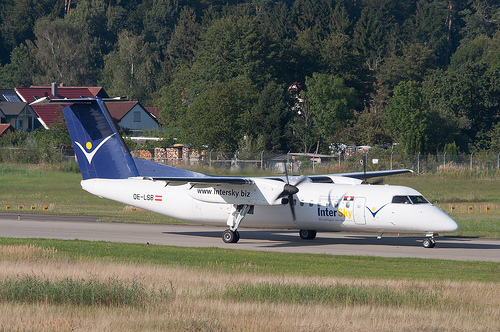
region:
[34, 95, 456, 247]
white plane with blue tail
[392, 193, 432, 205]
windshield of white plane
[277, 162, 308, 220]
white plane's right propellor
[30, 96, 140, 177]
tail of a white plane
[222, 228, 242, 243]
right rear landing gear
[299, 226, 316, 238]
left rear landing gear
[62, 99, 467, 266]
blue and white plane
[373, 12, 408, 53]
green leaves in brown trees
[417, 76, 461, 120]
green leaves in brown trees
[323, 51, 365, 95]
green leaves in brown trees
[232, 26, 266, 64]
green leaves in brown trees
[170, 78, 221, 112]
green leaves in brown trees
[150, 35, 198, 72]
green leaves in brown trees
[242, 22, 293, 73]
green leaves in brown trees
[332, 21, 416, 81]
green leaves in brown trees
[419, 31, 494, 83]
green leaves in brown trees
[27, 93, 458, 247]
a small airplane on a runway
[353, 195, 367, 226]
a door on an airplane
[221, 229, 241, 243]
a wheel on an airplane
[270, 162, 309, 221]
a spinning propeller on an airplane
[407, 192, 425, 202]
a cockpit window on an airplane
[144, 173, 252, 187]
a wing on an airplane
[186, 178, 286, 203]
an engine on the side of an airplane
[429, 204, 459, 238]
the nose on an airplane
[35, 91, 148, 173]
the tailwing on an airplane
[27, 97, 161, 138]
a house beside the airport runway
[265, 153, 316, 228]
Left propeller of airplane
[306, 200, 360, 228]
Name of airplane painted on side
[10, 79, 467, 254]
Propeller airplane on airport runway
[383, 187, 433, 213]
Windows of airplane cockpit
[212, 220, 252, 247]
Landing gear wheels of airplane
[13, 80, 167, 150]
Roofs of houses beside airport runway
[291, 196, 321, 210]
Passenger windows of propeller airplane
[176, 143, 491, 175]
Fencing along side of airport runway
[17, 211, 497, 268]
Tarmac of airport runway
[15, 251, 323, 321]
Brown and green grass beside airport runway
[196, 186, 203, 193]
blue letter on plane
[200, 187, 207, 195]
blue letter on plane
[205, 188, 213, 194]
blue letter on plane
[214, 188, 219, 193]
blue letter on plane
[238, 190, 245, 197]
blue letter on plane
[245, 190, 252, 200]
blue letter on plane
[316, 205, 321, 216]
blue letter on plane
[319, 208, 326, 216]
blue letter on plane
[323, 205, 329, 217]
blue letter on plane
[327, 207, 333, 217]
blue letter on plane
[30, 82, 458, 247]
A jet on a runway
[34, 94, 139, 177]
A blue painted tail on a jet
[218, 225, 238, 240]
Landing gear on a plane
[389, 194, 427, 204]
A front window on a plane